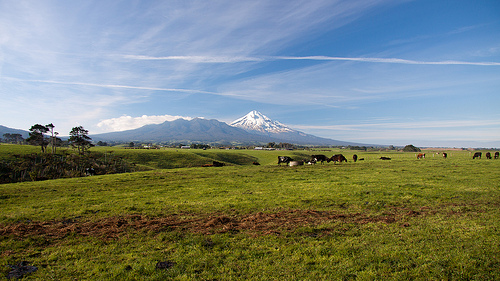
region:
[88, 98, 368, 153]
Mountain is in the background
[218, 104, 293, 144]
Mountain is snow capped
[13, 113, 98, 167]
Tall trees are in the background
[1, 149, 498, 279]
A landscape covered in grass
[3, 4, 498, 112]
Light colored clouds in the sky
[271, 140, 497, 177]
Animals are in the background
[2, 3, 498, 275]
Photo was taken in the daytime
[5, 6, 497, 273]
Photo was taken outdoors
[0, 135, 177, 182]
A small grass hill in the background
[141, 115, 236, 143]
Mountain is brown in color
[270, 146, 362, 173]
cows grazing on grass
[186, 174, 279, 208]
short green pasture grass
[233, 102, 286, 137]
snow on mountain top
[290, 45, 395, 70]
white exhaust line from plane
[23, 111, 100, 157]
trees with leaves on hill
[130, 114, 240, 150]
mountain range on horizon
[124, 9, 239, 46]
thin white clouds in sky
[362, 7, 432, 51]
blue of daytime sky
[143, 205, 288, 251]
bown grass in between green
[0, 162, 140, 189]
valley between two hills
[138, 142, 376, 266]
the wide field is wide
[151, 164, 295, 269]
the wide field is wide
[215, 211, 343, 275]
the wide field is wide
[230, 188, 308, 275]
the grass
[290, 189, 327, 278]
the grass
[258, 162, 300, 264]
the grass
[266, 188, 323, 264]
the grass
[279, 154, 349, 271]
the grass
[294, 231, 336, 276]
the grass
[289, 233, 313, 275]
the grass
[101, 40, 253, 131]
white clouds on sky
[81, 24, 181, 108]
white clouds on sky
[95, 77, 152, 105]
white clouds on sky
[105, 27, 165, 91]
white clouds on sky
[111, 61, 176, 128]
white clouds on sky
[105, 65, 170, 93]
white clouds on sky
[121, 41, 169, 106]
white clouds on sky